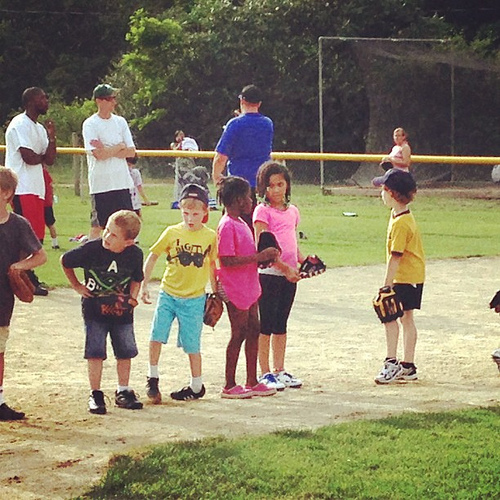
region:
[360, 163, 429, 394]
A boy in a yellow shirt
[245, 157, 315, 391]
A girl wearing a pink shirt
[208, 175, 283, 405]
A girl wearing a pink shirt and pink shoes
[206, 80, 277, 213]
A man in a blue shirt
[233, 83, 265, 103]
A black cap on the man's head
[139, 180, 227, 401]
A boy wearing a yellow shirt and blue shorts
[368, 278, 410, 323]
A yellow and black baseball glove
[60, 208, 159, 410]
A boy wearing a dark t-shirt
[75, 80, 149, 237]
A man wearing a white shirt and green hat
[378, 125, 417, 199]
A woman in the background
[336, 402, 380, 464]
part of a grass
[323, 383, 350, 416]
part of a floor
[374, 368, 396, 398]
part of a shoe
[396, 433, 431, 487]
part of a field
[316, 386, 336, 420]
part of a ground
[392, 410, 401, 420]
part of a ground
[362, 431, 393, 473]
part of a grasss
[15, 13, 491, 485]
adults and children on a playing field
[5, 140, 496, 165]
yellow pole across park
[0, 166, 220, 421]
children with mitts looking to side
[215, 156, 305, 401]
two girls in pink talking to each other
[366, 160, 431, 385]
boy looking away with crossed feet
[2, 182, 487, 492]
flat dirt path between grassy areas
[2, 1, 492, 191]
full trees behind park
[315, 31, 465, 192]
metal frame behind woman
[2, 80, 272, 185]
men listening to man talking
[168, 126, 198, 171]
woman on cellphone with baby on shoulder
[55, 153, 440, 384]
chilren in a line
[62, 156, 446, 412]
they are wearing shorts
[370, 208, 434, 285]
the jersey is yellow in colour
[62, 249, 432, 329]
they have gloves in the hands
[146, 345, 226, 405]
his leg is upturned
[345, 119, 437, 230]
a woman is seated down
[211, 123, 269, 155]
the shirt is brown in colour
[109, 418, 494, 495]
the grass is green in colour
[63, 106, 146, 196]
his shirt is white in coour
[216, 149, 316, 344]
the girls are talking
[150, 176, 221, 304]
Boy wearing a yellow shirt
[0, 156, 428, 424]
Kids standing on a baseball field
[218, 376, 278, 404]
A pair of pink shoes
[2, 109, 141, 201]
Two adults wearing white shirts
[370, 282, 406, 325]
A leather baseball glove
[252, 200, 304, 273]
A pink colored shirt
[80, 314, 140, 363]
A pair of jean shorts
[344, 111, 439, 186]
A large tree trunk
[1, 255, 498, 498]
Dirt on the field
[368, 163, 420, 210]
A hat on boy's head